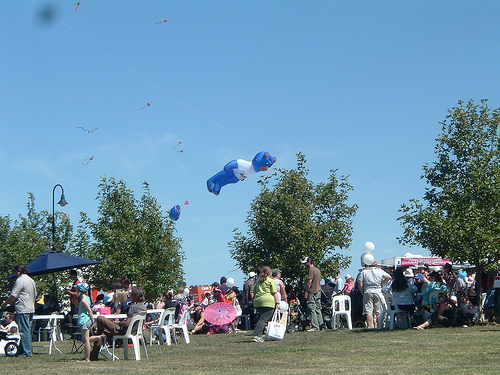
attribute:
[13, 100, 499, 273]
trees — green, tall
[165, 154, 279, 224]
balloon — big, blue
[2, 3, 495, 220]
sky — blue, massive, open, big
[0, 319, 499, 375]
grass — short, close, small, green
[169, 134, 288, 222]
kite — blue and white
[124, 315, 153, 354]
chair — white, plastic, lawn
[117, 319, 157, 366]
chair — plastic, white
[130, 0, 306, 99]
sky — clear, blue, cloudless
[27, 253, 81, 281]
umbrella — navy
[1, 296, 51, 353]
jeans — blue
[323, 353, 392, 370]
lawn — green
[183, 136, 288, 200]
teddy — blue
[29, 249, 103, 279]
umbrella — blue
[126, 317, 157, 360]
chair — white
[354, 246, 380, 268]
balloons — white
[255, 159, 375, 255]
tree — green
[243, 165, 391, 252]
tree — large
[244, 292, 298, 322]
woman — chubby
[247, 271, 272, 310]
shirt — green